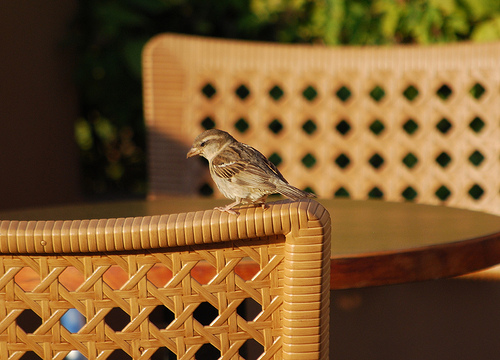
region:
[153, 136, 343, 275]
A bird sitting on a brown chair.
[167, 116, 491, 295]
Brown bird on brown chair with round table behind it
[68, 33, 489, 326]
Two chairs with round table and small bird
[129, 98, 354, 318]
A brown bird on brown chair with holes in back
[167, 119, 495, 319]
Small bird resting on a chair back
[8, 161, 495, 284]
Round table in between two chairs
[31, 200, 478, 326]
Plain, round table with beautifully designed chair.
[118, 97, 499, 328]
Small bird alone on chair with round table and another chair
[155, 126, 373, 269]
Small brown bird is perched on a chair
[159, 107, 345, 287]
A single bird perched on a chair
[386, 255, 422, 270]
edge of a table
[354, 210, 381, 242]
surface of a table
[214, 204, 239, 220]
leg of a table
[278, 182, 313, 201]
tail wing of a table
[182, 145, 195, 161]
beak of a bird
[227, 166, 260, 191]
part of some feathers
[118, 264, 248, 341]
holes on the chair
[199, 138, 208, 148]
left eye of the bird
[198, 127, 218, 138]
head of the bird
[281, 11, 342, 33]
part of a green fence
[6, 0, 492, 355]
Exterior shot, full sunlight.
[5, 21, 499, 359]
Outdoor scene, between spring and summer.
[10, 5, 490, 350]
Picture showing wildlife and man-made items.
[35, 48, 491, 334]
Patio chairs, table, and wild bird.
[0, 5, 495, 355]
Extreme close up of furniture and bird, with vegetation backing.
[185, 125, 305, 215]
Small bird, perched on chair rim, facing left.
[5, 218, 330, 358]
Close detail of wicker back of chair.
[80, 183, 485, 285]
Long, round, empty wooden table.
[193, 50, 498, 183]
Diamond spaces of front-facing, patio chair.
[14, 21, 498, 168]
Vegetation, backing patio of residence.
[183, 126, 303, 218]
bird on tan chair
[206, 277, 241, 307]
plastic weave on back of chair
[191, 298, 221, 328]
hole in chair design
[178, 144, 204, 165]
beak on bird's head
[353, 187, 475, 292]
round wood table outdoors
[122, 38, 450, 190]
chair behind wood table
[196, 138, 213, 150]
eye on bird's head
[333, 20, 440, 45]
vegetation behind tan chair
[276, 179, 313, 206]
tail feathers on bird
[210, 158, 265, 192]
wing on side of bird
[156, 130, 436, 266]
Bird sitting on the chair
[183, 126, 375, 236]
Bird's feet on the chair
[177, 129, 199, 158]
Bird's beak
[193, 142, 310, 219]
Feathers on the bird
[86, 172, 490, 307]
Patio set with a bird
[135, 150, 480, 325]
Patio set with chairs and table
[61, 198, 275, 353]
Wicker like chair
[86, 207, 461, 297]
Wooden table between the chairs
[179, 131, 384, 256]
Bird on the patio furniture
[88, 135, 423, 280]
Outside patio furniture and a bird